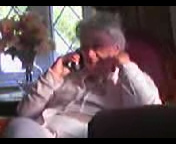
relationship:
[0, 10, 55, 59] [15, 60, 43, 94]
bouquet in vase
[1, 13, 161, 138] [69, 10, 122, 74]
man has head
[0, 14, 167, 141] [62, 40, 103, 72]
man on phone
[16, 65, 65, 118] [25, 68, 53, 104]
sleeve has wrinkles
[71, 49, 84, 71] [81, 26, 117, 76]
phone close face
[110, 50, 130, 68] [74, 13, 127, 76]
hand on face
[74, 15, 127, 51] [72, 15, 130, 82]
hair on head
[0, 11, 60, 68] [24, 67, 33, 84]
flowers on stems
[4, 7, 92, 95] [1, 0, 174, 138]
windows on wall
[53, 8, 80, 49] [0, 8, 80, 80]
pane on window glass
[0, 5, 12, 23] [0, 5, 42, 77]
pane on window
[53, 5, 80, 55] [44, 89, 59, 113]
pane on window glass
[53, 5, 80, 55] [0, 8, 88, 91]
pane on window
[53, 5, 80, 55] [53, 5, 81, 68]
pane on glass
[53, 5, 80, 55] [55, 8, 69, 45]
pane on window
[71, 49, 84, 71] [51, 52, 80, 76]
phone in hand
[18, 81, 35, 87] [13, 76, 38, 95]
rocks in vase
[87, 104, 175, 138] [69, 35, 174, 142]
arm of chair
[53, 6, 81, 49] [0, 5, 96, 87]
diamond shape on window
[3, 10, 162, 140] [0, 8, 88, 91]
woman in front of window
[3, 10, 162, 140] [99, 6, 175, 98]
woman in front of wall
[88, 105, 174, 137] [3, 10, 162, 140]
dark object in front of woman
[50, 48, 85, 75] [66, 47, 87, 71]
hand holding cellphone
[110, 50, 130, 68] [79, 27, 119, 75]
hand on side of face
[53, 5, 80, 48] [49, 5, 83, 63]
pattern on window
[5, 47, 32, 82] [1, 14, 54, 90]
stem on flowers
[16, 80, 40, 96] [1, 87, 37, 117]
vase on table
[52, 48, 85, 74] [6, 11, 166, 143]
hand of person